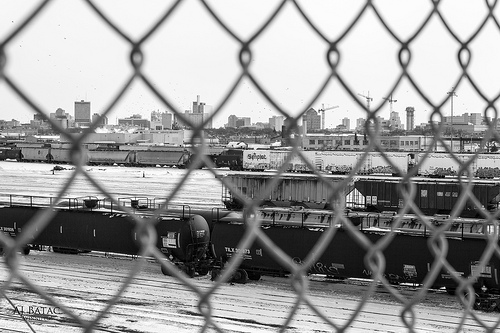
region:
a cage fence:
[50, 31, 325, 276]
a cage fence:
[168, 181, 286, 317]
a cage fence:
[129, 59, 278, 326]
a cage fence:
[169, 59, 387, 324]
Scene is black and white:
[0, 1, 498, 330]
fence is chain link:
[0, 0, 497, 330]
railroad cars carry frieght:
[1, 139, 498, 309]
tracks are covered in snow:
[0, 161, 499, 331]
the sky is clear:
[4, 0, 499, 130]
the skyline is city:
[0, 92, 497, 149]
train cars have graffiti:
[245, 154, 498, 176]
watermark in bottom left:
[10, 303, 64, 315]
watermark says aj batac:
[9, 303, 61, 313]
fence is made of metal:
[2, 2, 496, 329]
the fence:
[164, 117, 386, 325]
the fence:
[232, 160, 329, 302]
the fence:
[197, 115, 308, 319]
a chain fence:
[65, 108, 300, 273]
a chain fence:
[144, 33, 310, 325]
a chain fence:
[180, 179, 278, 298]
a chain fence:
[107, 129, 242, 311]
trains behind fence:
[101, 123, 400, 289]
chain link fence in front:
[34, 31, 450, 329]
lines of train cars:
[162, 143, 445, 298]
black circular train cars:
[63, 186, 448, 291]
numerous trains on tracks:
[3, 147, 221, 215]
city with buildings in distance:
[9, 83, 400, 152]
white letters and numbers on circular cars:
[203, 211, 255, 268]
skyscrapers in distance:
[62, 98, 212, 122]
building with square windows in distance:
[287, 125, 377, 148]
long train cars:
[21, 141, 197, 172]